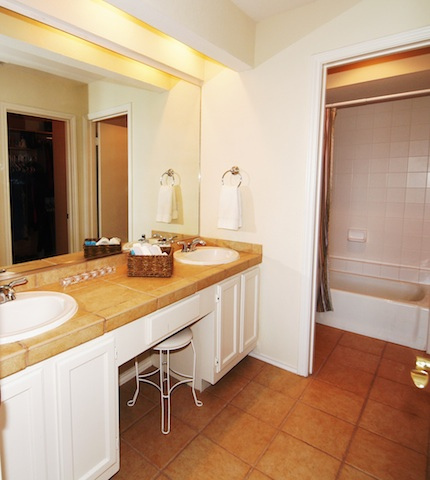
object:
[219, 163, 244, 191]
ring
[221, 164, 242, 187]
rack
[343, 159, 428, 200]
reflection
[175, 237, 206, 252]
faucet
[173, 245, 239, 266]
sink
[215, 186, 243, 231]
hand towel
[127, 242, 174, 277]
basket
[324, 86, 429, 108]
rod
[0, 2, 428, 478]
bathroom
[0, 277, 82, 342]
sink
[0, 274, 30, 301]
faucet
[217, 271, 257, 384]
cabinets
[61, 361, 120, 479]
cabinets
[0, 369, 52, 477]
cabinets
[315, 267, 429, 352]
bath tub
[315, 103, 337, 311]
curtain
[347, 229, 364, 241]
soap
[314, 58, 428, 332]
shower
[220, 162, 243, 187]
holder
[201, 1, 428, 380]
wall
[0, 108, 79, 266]
closet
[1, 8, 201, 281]
mirror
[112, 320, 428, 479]
floor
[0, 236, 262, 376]
counter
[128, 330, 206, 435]
stool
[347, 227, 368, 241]
soap holder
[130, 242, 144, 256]
product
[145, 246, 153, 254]
product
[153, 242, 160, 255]
product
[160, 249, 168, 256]
product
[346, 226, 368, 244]
place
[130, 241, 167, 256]
towel